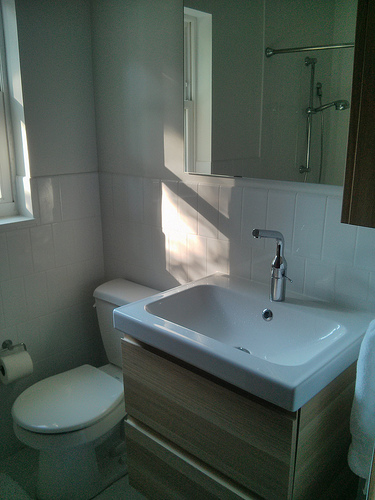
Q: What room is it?
A: It is a bathroom.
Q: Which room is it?
A: It is a bathroom.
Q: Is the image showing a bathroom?
A: Yes, it is showing a bathroom.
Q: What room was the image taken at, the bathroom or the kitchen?
A: It was taken at the bathroom.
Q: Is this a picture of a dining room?
A: No, the picture is showing a bathroom.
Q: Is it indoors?
A: Yes, it is indoors.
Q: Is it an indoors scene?
A: Yes, it is indoors.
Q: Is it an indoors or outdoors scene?
A: It is indoors.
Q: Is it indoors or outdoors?
A: It is indoors.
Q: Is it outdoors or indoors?
A: It is indoors.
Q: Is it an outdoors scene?
A: No, it is indoors.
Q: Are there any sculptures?
A: No, there are no sculptures.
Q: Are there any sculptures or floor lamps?
A: No, there are no sculptures or floor lamps.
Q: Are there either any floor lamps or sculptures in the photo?
A: No, there are no sculptures or floor lamps.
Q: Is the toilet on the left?
A: Yes, the toilet is on the left of the image.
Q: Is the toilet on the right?
A: No, the toilet is on the left of the image.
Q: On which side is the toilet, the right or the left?
A: The toilet is on the left of the image.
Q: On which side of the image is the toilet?
A: The toilet is on the left of the image.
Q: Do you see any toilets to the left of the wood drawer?
A: Yes, there is a toilet to the left of the drawer.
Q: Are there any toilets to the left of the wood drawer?
A: Yes, there is a toilet to the left of the drawer.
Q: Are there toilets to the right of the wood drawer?
A: No, the toilet is to the left of the drawer.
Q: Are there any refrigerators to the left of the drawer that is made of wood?
A: No, there is a toilet to the left of the drawer.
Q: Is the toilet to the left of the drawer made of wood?
A: Yes, the toilet is to the left of the drawer.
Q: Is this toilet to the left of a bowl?
A: No, the toilet is to the left of the drawer.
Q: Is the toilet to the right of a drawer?
A: No, the toilet is to the left of a drawer.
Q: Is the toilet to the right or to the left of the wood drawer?
A: The toilet is to the left of the drawer.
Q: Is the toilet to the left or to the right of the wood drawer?
A: The toilet is to the left of the drawer.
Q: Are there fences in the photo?
A: No, there are no fences.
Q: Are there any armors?
A: No, there are no armors.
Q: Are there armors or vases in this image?
A: No, there are no armors or vases.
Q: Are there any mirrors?
A: Yes, there is a mirror.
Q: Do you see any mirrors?
A: Yes, there is a mirror.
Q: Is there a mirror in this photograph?
A: Yes, there is a mirror.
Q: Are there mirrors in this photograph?
A: Yes, there is a mirror.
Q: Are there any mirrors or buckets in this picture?
A: Yes, there is a mirror.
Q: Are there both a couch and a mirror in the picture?
A: No, there is a mirror but no couches.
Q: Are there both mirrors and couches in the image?
A: No, there is a mirror but no couches.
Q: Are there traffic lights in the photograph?
A: No, there are no traffic lights.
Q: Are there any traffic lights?
A: No, there are no traffic lights.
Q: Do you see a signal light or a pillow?
A: No, there are no traffic lights or pillows.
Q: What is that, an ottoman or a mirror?
A: That is a mirror.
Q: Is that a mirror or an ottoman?
A: That is a mirror.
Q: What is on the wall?
A: The mirror is on the wall.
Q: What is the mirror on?
A: The mirror is on the wall.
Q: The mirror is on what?
A: The mirror is on the wall.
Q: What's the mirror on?
A: The mirror is on the wall.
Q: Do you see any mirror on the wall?
A: Yes, there is a mirror on the wall.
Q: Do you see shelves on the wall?
A: No, there is a mirror on the wall.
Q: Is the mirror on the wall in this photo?
A: Yes, the mirror is on the wall.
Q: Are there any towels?
A: Yes, there is a towel.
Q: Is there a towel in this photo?
A: Yes, there is a towel.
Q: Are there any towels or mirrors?
A: Yes, there is a towel.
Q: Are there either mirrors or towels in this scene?
A: Yes, there is a towel.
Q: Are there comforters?
A: No, there are no comforters.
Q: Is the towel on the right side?
A: Yes, the towel is on the right of the image.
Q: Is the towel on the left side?
A: No, the towel is on the right of the image.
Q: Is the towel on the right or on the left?
A: The towel is on the right of the image.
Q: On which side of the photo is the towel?
A: The towel is on the right of the image.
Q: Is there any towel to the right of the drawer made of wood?
A: Yes, there is a towel to the right of the drawer.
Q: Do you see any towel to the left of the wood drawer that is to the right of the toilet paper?
A: No, the towel is to the right of the drawer.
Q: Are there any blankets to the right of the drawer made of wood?
A: No, there is a towel to the right of the drawer.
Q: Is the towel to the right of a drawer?
A: Yes, the towel is to the right of a drawer.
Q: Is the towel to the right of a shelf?
A: No, the towel is to the right of a drawer.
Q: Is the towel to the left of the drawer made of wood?
A: No, the towel is to the right of the drawer.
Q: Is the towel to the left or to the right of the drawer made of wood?
A: The towel is to the right of the drawer.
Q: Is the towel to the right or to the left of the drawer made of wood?
A: The towel is to the right of the drawer.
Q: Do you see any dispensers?
A: No, there are no dispensers.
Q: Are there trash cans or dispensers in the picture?
A: No, there are no dispensers or trash cans.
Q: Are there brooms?
A: No, there are no brooms.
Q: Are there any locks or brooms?
A: No, there are no brooms or locks.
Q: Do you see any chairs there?
A: No, there are no chairs.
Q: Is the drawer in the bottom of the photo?
A: Yes, the drawer is in the bottom of the image.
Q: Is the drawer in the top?
A: No, the drawer is in the bottom of the image.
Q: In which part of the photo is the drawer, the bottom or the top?
A: The drawer is in the bottom of the image.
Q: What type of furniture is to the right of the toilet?
A: The piece of furniture is a drawer.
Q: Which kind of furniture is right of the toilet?
A: The piece of furniture is a drawer.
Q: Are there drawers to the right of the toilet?
A: Yes, there is a drawer to the right of the toilet.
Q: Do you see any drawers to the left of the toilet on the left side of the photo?
A: No, the drawer is to the right of the toilet.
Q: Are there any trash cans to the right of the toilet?
A: No, there is a drawer to the right of the toilet.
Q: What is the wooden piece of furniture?
A: The piece of furniture is a drawer.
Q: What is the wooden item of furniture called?
A: The piece of furniture is a drawer.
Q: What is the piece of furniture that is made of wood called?
A: The piece of furniture is a drawer.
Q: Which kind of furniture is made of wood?
A: The furniture is a drawer.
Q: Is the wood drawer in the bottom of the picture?
A: Yes, the drawer is in the bottom of the image.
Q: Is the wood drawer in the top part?
A: No, the drawer is in the bottom of the image.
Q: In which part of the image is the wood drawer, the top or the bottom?
A: The drawer is in the bottom of the image.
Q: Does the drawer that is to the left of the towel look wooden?
A: Yes, the drawer is wooden.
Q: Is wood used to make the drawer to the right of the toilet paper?
A: Yes, the drawer is made of wood.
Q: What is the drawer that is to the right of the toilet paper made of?
A: The drawer is made of wood.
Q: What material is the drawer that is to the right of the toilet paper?
A: The drawer is made of wood.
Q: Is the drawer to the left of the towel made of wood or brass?
A: The drawer is made of wood.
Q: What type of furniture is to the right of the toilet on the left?
A: The piece of furniture is a drawer.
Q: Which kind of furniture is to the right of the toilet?
A: The piece of furniture is a drawer.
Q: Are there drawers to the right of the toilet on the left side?
A: Yes, there is a drawer to the right of the toilet.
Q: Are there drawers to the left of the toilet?
A: No, the drawer is to the right of the toilet.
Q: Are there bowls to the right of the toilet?
A: No, there is a drawer to the right of the toilet.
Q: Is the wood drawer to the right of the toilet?
A: Yes, the drawer is to the right of the toilet.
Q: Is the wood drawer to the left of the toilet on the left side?
A: No, the drawer is to the right of the toilet.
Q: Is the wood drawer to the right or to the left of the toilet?
A: The drawer is to the right of the toilet.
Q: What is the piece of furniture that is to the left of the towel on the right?
A: The piece of furniture is a drawer.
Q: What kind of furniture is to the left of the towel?
A: The piece of furniture is a drawer.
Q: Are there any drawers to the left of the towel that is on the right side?
A: Yes, there is a drawer to the left of the towel.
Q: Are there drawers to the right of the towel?
A: No, the drawer is to the left of the towel.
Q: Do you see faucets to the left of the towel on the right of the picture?
A: No, there is a drawer to the left of the towel.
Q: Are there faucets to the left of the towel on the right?
A: No, there is a drawer to the left of the towel.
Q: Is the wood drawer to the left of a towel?
A: Yes, the drawer is to the left of a towel.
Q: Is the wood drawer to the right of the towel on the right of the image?
A: No, the drawer is to the left of the towel.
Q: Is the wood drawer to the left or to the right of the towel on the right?
A: The drawer is to the left of the towel.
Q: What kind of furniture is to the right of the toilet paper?
A: The piece of furniture is a drawer.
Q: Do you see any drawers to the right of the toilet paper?
A: Yes, there is a drawer to the right of the toilet paper.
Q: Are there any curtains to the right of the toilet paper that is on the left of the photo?
A: No, there is a drawer to the right of the toilet paper.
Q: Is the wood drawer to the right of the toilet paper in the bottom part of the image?
A: Yes, the drawer is to the right of the toilet paper.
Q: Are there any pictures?
A: No, there are no pictures.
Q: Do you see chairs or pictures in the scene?
A: No, there are no pictures or chairs.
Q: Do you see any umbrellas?
A: No, there are no umbrellas.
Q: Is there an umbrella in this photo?
A: No, there are no umbrellas.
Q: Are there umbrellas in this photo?
A: No, there are no umbrellas.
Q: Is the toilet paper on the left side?
A: Yes, the toilet paper is on the left of the image.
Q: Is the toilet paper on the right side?
A: No, the toilet paper is on the left of the image.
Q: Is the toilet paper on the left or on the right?
A: The toilet paper is on the left of the image.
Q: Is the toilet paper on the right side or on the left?
A: The toilet paper is on the left of the image.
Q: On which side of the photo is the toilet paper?
A: The toilet paper is on the left of the image.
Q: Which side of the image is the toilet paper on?
A: The toilet paper is on the left of the image.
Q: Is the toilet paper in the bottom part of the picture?
A: Yes, the toilet paper is in the bottom of the image.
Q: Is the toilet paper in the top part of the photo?
A: No, the toilet paper is in the bottom of the image.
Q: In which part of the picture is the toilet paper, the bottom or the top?
A: The toilet paper is in the bottom of the image.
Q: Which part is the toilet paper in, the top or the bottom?
A: The toilet paper is in the bottom of the image.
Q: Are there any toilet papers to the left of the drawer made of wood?
A: Yes, there is a toilet paper to the left of the drawer.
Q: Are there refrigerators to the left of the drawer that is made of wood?
A: No, there is a toilet paper to the left of the drawer.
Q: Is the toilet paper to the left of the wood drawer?
A: Yes, the toilet paper is to the left of the drawer.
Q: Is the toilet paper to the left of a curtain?
A: No, the toilet paper is to the left of the drawer.